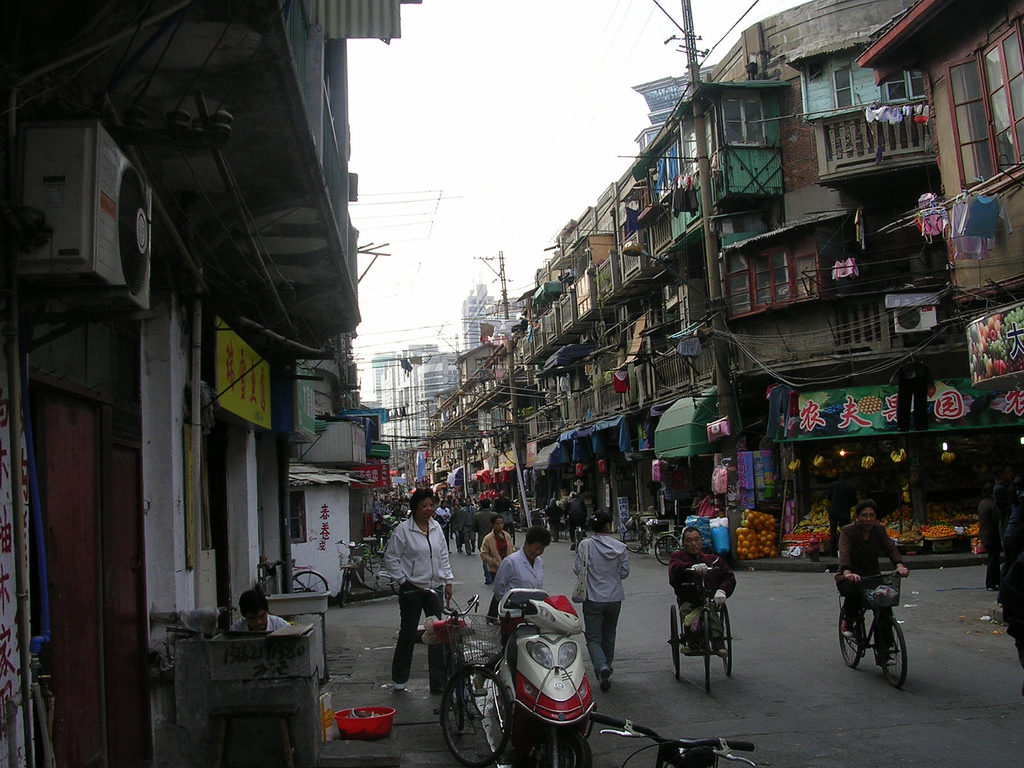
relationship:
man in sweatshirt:
[655, 513, 736, 619] [672, 551, 737, 580]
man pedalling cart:
[655, 513, 736, 619] [663, 593, 757, 689]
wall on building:
[378, 345, 472, 456] [365, 321, 459, 427]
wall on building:
[378, 345, 473, 456] [376, 336, 478, 430]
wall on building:
[378, 345, 473, 456] [352, 310, 504, 468]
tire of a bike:
[426, 655, 522, 759] [413, 586, 621, 759]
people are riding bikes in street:
[611, 380, 988, 707] [276, 231, 977, 648]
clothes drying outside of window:
[761, 109, 991, 274] [907, 295, 983, 391]